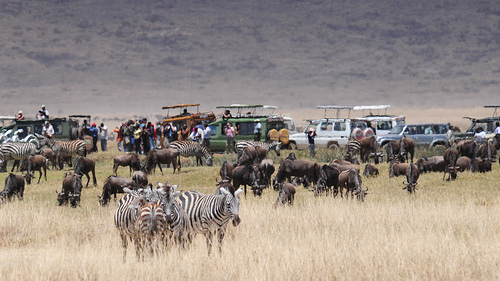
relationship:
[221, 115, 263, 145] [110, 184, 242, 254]
people watching animals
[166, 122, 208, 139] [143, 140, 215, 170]
people watching animals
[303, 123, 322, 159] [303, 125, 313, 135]
person wearing hat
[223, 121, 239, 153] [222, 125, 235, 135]
person wearing shirt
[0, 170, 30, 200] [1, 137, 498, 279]
animal grazing in grass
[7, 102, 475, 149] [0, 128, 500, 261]
people watching animals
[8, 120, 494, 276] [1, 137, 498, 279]
animals in grass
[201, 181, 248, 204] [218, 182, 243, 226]
ears on head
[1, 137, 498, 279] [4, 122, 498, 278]
grass on ground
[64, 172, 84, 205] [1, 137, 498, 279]
animal grazing in grass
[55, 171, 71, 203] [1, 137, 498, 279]
animal grazing in grass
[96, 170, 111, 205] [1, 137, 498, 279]
animal grazing in grass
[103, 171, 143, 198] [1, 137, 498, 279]
animal grazing in grass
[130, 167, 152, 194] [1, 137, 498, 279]
animal grazing in grass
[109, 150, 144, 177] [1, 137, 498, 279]
animal grazing in grass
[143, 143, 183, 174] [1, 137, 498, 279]
animal grazing in grass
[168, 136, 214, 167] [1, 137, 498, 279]
animal grazing in grass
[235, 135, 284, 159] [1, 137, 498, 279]
animal grazing in grass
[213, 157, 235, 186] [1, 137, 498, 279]
animal grazing in grass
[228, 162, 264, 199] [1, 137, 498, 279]
animal grazing in grass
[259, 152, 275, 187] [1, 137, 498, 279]
animal grazing in grass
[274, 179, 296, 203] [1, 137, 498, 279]
animal grazing in grass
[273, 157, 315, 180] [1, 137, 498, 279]
animal grazing in grass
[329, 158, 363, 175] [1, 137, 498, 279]
animal grazing in grass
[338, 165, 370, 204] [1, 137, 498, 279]
animal grazing in grass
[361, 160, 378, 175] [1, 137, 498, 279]
animal grazing in grass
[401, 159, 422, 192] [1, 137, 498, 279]
animal grazing in grass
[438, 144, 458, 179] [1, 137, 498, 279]
animal grazing in grass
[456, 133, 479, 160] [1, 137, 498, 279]
animal grazing in grass